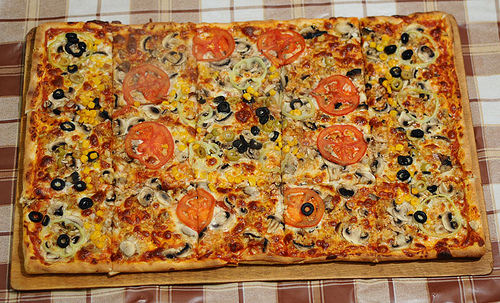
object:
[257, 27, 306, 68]
tomato slice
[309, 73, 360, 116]
tomato slice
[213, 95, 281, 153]
olives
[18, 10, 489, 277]
pizza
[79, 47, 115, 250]
corn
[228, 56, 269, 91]
onion ring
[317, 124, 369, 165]
tomato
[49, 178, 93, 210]
olives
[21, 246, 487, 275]
crust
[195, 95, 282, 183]
middle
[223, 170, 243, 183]
topping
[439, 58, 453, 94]
sauce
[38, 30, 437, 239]
toppings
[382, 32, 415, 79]
olives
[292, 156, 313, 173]
cheese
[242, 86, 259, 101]
corn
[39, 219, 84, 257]
onions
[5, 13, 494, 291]
board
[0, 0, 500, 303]
table cloth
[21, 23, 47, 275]
crust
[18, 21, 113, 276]
slices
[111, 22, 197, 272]
slices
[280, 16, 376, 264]
slices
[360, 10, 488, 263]
slices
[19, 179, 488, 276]
slices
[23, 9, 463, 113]
slices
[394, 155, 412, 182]
olives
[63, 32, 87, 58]
olives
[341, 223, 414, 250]
mushrooms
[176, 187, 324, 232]
tomatoes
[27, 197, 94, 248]
olives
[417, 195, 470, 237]
mushroom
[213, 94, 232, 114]
black olive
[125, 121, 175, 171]
tomato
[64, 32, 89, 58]
black olive